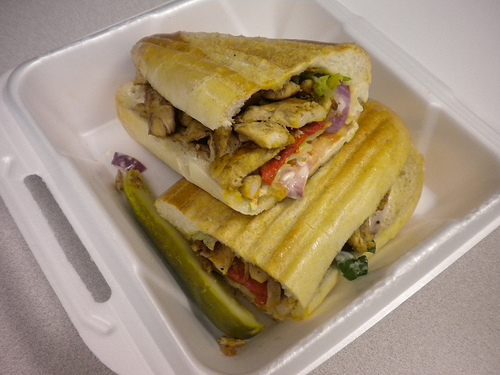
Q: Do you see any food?
A: Yes, there is food.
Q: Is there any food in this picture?
A: Yes, there is food.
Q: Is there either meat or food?
A: Yes, there is food.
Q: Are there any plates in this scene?
A: No, there are no plates.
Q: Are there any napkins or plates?
A: No, there are no plates or napkins.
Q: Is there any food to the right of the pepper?
A: Yes, there is food to the right of the pepper.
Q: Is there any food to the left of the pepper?
A: No, the food is to the right of the pepper.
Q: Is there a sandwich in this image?
A: Yes, there is a sandwich.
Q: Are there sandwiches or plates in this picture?
A: Yes, there is a sandwich.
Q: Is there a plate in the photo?
A: No, there are no plates.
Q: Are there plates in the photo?
A: No, there are no plates.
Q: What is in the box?
A: The sandwich is in the box.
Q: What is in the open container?
A: The sandwich is in the box.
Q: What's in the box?
A: The sandwich is in the box.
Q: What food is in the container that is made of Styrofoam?
A: The food is a sandwich.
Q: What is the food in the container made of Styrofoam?
A: The food is a sandwich.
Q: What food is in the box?
A: The food is a sandwich.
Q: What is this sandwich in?
A: The sandwich is in the box.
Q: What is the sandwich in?
A: The sandwich is in the box.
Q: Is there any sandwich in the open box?
A: Yes, there is a sandwich in the box.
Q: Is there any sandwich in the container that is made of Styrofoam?
A: Yes, there is a sandwich in the box.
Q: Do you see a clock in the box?
A: No, there is a sandwich in the box.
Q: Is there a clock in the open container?
A: No, there is a sandwich in the box.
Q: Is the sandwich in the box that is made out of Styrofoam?
A: Yes, the sandwich is in the box.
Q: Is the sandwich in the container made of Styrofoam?
A: Yes, the sandwich is in the box.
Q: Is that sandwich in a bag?
A: No, the sandwich is in the box.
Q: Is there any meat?
A: Yes, there is meat.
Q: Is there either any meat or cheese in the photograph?
A: Yes, there is meat.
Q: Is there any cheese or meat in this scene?
A: Yes, there is meat.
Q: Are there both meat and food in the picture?
A: Yes, there are both meat and food.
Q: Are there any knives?
A: No, there are no knives.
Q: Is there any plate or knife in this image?
A: No, there are no knives or plates.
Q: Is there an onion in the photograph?
A: Yes, there is an onion.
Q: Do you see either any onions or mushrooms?
A: Yes, there is an onion.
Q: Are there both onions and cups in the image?
A: No, there is an onion but no cups.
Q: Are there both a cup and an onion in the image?
A: No, there is an onion but no cups.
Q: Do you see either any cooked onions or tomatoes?
A: Yes, there is a cooked onion.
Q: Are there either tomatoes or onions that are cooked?
A: Yes, the onion is cooked.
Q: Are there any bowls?
A: No, there are no bowls.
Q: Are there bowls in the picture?
A: No, there are no bowls.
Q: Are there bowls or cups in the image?
A: No, there are no bowls or cups.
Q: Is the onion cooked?
A: Yes, the onion is cooked.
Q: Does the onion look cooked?
A: Yes, the onion is cooked.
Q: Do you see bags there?
A: No, there are no bags.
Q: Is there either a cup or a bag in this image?
A: No, there are no bags or cups.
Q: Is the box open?
A: Yes, the box is open.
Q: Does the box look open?
A: Yes, the box is open.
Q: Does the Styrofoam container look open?
A: Yes, the box is open.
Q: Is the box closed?
A: No, the box is open.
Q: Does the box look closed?
A: No, the box is open.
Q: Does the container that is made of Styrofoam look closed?
A: No, the box is open.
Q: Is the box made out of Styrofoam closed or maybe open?
A: The box is open.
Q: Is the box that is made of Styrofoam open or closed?
A: The box is open.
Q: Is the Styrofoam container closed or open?
A: The box is open.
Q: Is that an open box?
A: Yes, that is an open box.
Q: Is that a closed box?
A: No, that is an open box.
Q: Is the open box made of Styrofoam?
A: Yes, the box is made of styrofoam.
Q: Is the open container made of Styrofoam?
A: Yes, the box is made of styrofoam.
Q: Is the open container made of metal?
A: No, the box is made of styrofoam.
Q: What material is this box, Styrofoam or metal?
A: The box is made of styrofoam.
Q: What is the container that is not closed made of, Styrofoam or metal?
A: The box is made of styrofoam.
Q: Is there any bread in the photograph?
A: Yes, there is a bread.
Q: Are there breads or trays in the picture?
A: Yes, there is a bread.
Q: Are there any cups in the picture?
A: No, there are no cups.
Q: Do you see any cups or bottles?
A: No, there are no cups or bottles.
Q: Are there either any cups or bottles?
A: No, there are no cups or bottles.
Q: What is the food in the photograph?
A: The food is a bread.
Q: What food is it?
A: The food is a bread.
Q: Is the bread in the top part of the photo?
A: Yes, the bread is in the top of the image.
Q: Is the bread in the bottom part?
A: No, the bread is in the top of the image.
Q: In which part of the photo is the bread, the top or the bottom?
A: The bread is in the top of the image.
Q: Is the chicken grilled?
A: Yes, the chicken is grilled.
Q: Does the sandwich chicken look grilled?
A: Yes, the chicken is grilled.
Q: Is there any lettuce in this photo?
A: Yes, there is lettuce.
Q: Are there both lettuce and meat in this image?
A: Yes, there are both lettuce and meat.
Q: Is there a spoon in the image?
A: No, there are no spoons.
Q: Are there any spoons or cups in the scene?
A: No, there are no spoons or cups.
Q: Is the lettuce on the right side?
A: Yes, the lettuce is on the right of the image.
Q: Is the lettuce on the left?
A: No, the lettuce is on the right of the image.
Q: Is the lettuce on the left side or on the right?
A: The lettuce is on the right of the image.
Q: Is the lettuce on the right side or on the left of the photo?
A: The lettuce is on the right of the image.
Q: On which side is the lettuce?
A: The lettuce is on the right of the image.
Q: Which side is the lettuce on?
A: The lettuce is on the right of the image.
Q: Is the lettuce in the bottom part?
A: Yes, the lettuce is in the bottom of the image.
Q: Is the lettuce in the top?
A: No, the lettuce is in the bottom of the image.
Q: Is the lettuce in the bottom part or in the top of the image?
A: The lettuce is in the bottom of the image.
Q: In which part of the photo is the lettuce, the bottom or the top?
A: The lettuce is in the bottom of the image.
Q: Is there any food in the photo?
A: Yes, there is food.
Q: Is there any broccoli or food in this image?
A: Yes, there is food.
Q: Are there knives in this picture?
A: No, there are no knives.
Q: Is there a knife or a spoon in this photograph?
A: No, there are no knives or spoons.